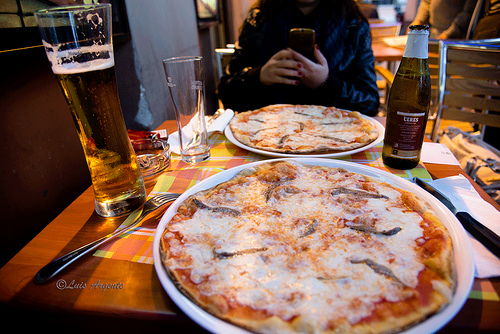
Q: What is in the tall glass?
A: Beer.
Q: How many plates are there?
A: 2.